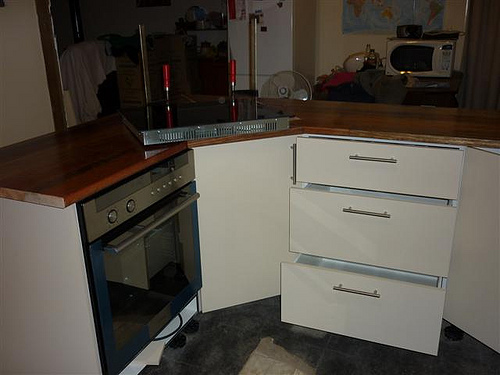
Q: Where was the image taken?
A: It was taken at the kitchen.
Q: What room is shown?
A: It is a kitchen.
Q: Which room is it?
A: It is a kitchen.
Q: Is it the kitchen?
A: Yes, it is the kitchen.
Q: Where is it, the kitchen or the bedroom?
A: It is the kitchen.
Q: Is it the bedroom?
A: No, it is the kitchen.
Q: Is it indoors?
A: Yes, it is indoors.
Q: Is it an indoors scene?
A: Yes, it is indoors.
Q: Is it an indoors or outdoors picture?
A: It is indoors.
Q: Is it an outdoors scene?
A: No, it is indoors.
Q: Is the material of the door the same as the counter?
A: No, the door is made of glass and the counter is made of wood.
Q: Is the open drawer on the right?
A: Yes, the drawer is on the right of the image.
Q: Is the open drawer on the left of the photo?
A: No, the drawer is on the right of the image.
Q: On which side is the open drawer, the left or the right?
A: The drawer is on the right of the image.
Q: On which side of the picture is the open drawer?
A: The drawer is on the right of the image.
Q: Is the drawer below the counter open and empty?
A: Yes, the drawer is open and empty.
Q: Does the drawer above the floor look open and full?
A: No, the drawer is open but empty.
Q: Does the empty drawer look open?
A: Yes, the drawer is open.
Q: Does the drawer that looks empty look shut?
A: No, the drawer is open.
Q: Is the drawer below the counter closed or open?
A: The drawer is open.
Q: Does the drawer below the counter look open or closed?
A: The drawer is open.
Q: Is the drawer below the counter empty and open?
A: Yes, the drawer is empty and open.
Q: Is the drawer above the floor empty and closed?
A: No, the drawer is empty but open.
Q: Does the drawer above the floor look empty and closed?
A: No, the drawer is empty but open.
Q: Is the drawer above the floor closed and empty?
A: No, the drawer is empty but open.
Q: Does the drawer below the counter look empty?
A: Yes, the drawer is empty.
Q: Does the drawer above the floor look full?
A: No, the drawer is empty.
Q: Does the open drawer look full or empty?
A: The drawer is empty.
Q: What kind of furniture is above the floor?
A: The piece of furniture is a drawer.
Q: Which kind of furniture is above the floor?
A: The piece of furniture is a drawer.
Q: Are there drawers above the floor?
A: Yes, there is a drawer above the floor.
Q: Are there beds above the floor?
A: No, there is a drawer above the floor.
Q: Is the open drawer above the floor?
A: Yes, the drawer is above the floor.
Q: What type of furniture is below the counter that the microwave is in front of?
A: The piece of furniture is a drawer.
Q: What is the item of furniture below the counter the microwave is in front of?
A: The piece of furniture is a drawer.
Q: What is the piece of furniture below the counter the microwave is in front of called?
A: The piece of furniture is a drawer.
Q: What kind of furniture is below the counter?
A: The piece of furniture is a drawer.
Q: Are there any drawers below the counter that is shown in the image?
A: Yes, there is a drawer below the counter.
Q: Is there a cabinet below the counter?
A: No, there is a drawer below the counter.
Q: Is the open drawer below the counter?
A: Yes, the drawer is below the counter.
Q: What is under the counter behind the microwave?
A: The drawer is under the counter.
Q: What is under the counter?
A: The drawer is under the counter.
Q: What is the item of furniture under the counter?
A: The piece of furniture is a drawer.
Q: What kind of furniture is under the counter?
A: The piece of furniture is a drawer.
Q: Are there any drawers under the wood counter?
A: Yes, there is a drawer under the counter.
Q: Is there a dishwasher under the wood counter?
A: No, there is a drawer under the counter.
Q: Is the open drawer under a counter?
A: Yes, the drawer is under a counter.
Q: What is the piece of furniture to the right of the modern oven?
A: The piece of furniture is a drawer.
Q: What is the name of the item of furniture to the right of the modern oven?
A: The piece of furniture is a drawer.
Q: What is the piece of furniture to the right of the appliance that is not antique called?
A: The piece of furniture is a drawer.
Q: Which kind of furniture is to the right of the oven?
A: The piece of furniture is a drawer.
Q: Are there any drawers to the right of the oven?
A: Yes, there is a drawer to the right of the oven.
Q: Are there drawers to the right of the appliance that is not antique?
A: Yes, there is a drawer to the right of the oven.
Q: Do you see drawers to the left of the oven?
A: No, the drawer is to the right of the oven.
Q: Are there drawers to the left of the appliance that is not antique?
A: No, the drawer is to the right of the oven.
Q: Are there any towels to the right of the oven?
A: No, there is a drawer to the right of the oven.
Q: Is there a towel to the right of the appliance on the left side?
A: No, there is a drawer to the right of the oven.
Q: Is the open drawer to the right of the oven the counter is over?
A: Yes, the drawer is to the right of the oven.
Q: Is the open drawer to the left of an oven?
A: No, the drawer is to the right of an oven.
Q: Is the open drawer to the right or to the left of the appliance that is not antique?
A: The drawer is to the right of the oven.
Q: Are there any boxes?
A: No, there are no boxes.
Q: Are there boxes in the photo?
A: No, there are no boxes.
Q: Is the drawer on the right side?
A: Yes, the drawer is on the right of the image.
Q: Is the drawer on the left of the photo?
A: No, the drawer is on the right of the image.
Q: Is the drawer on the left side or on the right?
A: The drawer is on the right of the image.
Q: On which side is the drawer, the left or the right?
A: The drawer is on the right of the image.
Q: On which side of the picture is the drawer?
A: The drawer is on the right of the image.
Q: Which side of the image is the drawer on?
A: The drawer is on the right of the image.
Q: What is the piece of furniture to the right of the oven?
A: The piece of furniture is a drawer.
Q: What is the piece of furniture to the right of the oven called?
A: The piece of furniture is a drawer.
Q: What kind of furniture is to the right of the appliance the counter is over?
A: The piece of furniture is a drawer.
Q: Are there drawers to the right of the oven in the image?
A: Yes, there is a drawer to the right of the oven.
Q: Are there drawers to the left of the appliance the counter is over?
A: No, the drawer is to the right of the oven.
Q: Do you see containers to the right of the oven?
A: No, there is a drawer to the right of the oven.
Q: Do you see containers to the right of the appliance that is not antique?
A: No, there is a drawer to the right of the oven.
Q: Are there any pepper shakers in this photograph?
A: No, there are no pepper shakers.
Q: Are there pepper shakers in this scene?
A: No, there are no pepper shakers.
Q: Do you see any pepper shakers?
A: No, there are no pepper shakers.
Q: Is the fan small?
A: Yes, the fan is small.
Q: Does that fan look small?
A: Yes, the fan is small.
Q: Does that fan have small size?
A: Yes, the fan is small.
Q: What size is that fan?
A: The fan is small.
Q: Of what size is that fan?
A: The fan is small.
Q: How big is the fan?
A: The fan is small.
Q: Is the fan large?
A: No, the fan is small.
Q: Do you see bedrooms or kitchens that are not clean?
A: No, there is a kitchen but it is clean.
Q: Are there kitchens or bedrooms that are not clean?
A: No, there is a kitchen but it is clean.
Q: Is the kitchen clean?
A: Yes, the kitchen is clean.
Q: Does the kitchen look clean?
A: Yes, the kitchen is clean.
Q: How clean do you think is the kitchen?
A: The kitchen is clean.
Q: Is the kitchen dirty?
A: No, the kitchen is clean.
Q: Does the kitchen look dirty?
A: No, the kitchen is clean.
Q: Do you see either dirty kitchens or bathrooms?
A: No, there is a kitchen but it is clean.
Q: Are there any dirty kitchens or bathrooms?
A: No, there is a kitchen but it is clean.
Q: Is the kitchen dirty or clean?
A: The kitchen is clean.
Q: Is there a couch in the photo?
A: No, there are no couches.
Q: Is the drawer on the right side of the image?
A: Yes, the drawer is on the right of the image.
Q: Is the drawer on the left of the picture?
A: No, the drawer is on the right of the image.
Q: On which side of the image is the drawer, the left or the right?
A: The drawer is on the right of the image.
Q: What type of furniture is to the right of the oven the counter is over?
A: The piece of furniture is a drawer.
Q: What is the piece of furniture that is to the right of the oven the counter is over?
A: The piece of furniture is a drawer.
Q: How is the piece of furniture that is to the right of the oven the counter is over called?
A: The piece of furniture is a drawer.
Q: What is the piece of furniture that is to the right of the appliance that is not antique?
A: The piece of furniture is a drawer.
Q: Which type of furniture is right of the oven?
A: The piece of furniture is a drawer.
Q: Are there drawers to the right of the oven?
A: Yes, there is a drawer to the right of the oven.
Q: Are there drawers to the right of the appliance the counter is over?
A: Yes, there is a drawer to the right of the oven.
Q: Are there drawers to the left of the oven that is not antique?
A: No, the drawer is to the right of the oven.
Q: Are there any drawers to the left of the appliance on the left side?
A: No, the drawer is to the right of the oven.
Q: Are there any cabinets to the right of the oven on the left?
A: No, there is a drawer to the right of the oven.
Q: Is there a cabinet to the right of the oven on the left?
A: No, there is a drawer to the right of the oven.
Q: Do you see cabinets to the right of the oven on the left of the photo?
A: No, there is a drawer to the right of the oven.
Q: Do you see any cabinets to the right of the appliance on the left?
A: No, there is a drawer to the right of the oven.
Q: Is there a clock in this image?
A: No, there are no clocks.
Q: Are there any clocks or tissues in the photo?
A: No, there are no clocks or tissues.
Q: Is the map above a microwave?
A: Yes, the map is above a microwave.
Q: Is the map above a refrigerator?
A: No, the map is above a microwave.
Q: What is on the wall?
A: The map is on the wall.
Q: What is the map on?
A: The map is on the wall.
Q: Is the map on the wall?
A: Yes, the map is on the wall.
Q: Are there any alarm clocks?
A: No, there are no alarm clocks.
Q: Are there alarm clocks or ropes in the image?
A: No, there are no alarm clocks or ropes.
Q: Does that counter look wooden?
A: Yes, the counter is wooden.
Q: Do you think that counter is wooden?
A: Yes, the counter is wooden.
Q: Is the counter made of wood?
A: Yes, the counter is made of wood.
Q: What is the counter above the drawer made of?
A: The counter is made of wood.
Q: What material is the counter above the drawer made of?
A: The counter is made of wood.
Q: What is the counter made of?
A: The counter is made of wood.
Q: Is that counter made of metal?
A: No, the counter is made of wood.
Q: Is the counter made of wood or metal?
A: The counter is made of wood.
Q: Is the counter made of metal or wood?
A: The counter is made of wood.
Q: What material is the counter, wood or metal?
A: The counter is made of wood.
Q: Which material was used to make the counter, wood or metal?
A: The counter is made of wood.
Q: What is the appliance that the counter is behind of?
A: The appliance is a microwave.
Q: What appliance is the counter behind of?
A: The counter is behind the microwave.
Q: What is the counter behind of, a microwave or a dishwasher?
A: The counter is behind a microwave.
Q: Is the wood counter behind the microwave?
A: Yes, the counter is behind the microwave.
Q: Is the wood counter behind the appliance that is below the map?
A: Yes, the counter is behind the microwave.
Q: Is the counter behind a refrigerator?
A: No, the counter is behind the microwave.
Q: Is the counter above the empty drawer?
A: Yes, the counter is above the drawer.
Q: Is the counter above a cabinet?
A: No, the counter is above the drawer.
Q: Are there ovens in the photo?
A: Yes, there is an oven.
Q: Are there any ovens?
A: Yes, there is an oven.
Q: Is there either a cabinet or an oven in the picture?
A: Yes, there is an oven.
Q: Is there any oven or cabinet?
A: Yes, there is an oven.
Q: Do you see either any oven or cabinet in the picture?
A: Yes, there is an oven.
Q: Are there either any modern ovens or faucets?
A: Yes, there is a modern oven.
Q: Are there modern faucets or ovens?
A: Yes, there is a modern oven.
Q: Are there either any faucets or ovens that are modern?
A: Yes, the oven is modern.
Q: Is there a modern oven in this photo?
A: Yes, there is a modern oven.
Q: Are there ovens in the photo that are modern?
A: Yes, there is an oven that is modern.